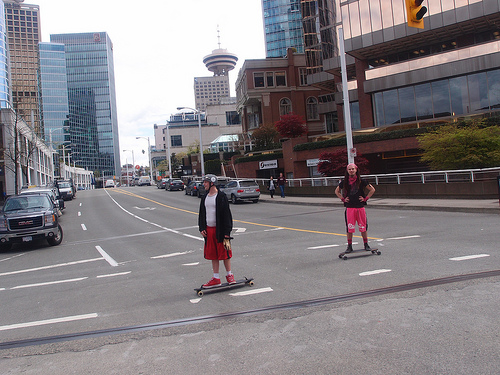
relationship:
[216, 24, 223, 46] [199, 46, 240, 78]
pole top of building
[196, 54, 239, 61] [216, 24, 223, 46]
ring on pole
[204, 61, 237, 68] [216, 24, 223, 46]
ring on pole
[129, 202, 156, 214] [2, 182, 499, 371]
arrow in road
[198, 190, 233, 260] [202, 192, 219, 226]
clothes has on tank top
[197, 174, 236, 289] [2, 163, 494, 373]
guy in street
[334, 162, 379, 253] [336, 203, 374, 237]
guy has shorts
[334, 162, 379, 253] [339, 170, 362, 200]
guy has hair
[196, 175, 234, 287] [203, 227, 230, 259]
guy has shorts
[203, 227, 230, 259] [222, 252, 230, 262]
shorts with stripe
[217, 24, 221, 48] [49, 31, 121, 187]
pole on top building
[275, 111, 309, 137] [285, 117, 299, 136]
leaves with leaves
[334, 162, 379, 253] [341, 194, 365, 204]
guy has hands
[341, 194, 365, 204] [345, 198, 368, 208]
hands on hips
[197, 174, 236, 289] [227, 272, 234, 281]
guy has shoe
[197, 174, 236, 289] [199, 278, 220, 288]
guy has shoe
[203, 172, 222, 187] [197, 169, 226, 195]
helmet on man's head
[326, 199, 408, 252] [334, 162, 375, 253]
shorts on guy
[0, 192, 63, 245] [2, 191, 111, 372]
car parked near sidewalk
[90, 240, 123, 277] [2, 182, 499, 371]
line on road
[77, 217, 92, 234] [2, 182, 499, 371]
line on road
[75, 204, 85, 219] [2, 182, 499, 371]
line on road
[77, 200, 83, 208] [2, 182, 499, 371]
line on road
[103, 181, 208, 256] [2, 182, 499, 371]
line on road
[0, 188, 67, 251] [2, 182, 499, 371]
car on road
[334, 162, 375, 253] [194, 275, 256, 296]
guy on skateboarder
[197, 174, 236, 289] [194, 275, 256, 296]
guy on skateboarder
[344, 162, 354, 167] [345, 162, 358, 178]
bandana on head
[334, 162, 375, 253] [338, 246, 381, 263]
guy standing on skateboard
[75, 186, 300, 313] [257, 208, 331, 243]
paved street with yellow lines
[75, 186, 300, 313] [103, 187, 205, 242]
paved street with line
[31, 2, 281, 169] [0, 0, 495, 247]
sky over city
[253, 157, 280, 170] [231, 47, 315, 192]
sign on building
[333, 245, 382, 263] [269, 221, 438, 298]
skateboard on street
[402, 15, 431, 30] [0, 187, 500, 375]
light above ground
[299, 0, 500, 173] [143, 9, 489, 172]
building on building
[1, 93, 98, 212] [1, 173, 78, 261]
short buildings behind cars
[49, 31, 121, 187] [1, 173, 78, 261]
building behind cars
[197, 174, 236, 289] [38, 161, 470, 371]
guy crossing street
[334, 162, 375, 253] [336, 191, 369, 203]
guy with hands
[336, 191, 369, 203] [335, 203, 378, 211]
hands at waist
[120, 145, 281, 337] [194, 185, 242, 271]
skateboarder in clothes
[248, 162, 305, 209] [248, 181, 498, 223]
people on sidewalk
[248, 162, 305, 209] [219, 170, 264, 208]
people past car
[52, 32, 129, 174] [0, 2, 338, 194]
building in distance